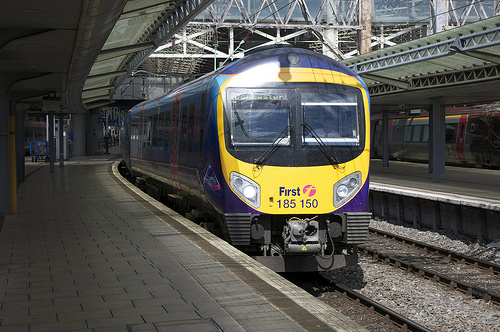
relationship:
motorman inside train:
[306, 115, 341, 137] [124, 40, 380, 244]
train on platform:
[128, 43, 401, 289] [0, 145, 369, 331]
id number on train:
[265, 177, 320, 208] [120, 39, 383, 271]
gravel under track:
[379, 274, 446, 312] [376, 278, 482, 328]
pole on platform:
[5, 112, 17, 223] [0, 145, 369, 331]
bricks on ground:
[0, 211, 235, 328] [59, 154, 499, 326]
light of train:
[227, 169, 265, 214] [121, 34, 386, 298]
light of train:
[325, 169, 373, 211] [121, 34, 386, 298]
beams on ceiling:
[142, 1, 499, 64] [154, 4, 407, 66]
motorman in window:
[308, 114, 341, 137] [298, 90, 358, 145]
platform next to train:
[14, 110, 150, 312] [155, 54, 377, 229]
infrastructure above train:
[149, 2, 497, 124] [120, 39, 383, 271]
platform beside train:
[370, 158, 498, 214] [120, 39, 383, 271]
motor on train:
[220, 209, 370, 285] [120, 39, 383, 271]